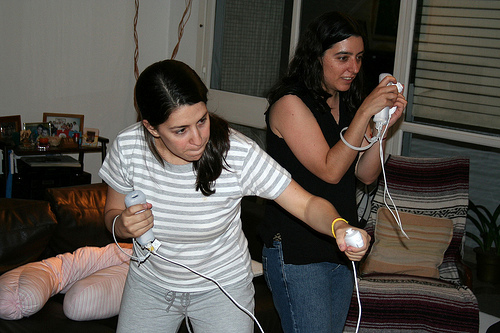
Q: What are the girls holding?
A: Remote controls.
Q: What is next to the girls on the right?
A: Sofa.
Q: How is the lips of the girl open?
A: Tightly closed.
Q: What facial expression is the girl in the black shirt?
A: Smiling.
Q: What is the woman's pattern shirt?
A: Striped.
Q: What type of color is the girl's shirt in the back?
A: Black.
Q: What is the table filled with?
A: Pictures.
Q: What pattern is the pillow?
A: Striped.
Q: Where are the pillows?
A: On the couch.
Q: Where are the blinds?
A: On the window.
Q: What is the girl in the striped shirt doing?
A: Play Wii.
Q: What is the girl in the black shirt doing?
A: Playing Wii.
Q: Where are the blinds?
A: On the window.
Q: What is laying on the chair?
A: A striped blanket.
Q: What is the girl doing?
A: Playing Wii.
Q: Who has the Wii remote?
A: The black haired girl.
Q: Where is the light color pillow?
A: On the chair.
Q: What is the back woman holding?
A: Wii remote.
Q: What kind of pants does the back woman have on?
A: Jeans.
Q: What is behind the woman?
A: White wall.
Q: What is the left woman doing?
A: Playing Wii.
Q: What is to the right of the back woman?
A: Chair with blanket and pillow.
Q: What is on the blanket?
A: Pillow.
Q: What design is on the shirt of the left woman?
A: Stripes.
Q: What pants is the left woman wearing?
A: Sweatpants.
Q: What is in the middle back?
A: Windows.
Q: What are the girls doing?
A: Playing wii.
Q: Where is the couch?
A: Behind the girls.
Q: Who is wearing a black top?
A: A girl.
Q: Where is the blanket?
A: On the chair.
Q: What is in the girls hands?
A: Remotes.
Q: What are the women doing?
A: Playing video games.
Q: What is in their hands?
A: Game controls.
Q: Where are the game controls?
A: In the girls hands.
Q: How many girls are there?
A: Two.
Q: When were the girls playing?
A: Night time.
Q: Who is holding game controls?
A: Two girls.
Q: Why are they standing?
A: To play video games.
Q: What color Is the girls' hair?
A: Black.